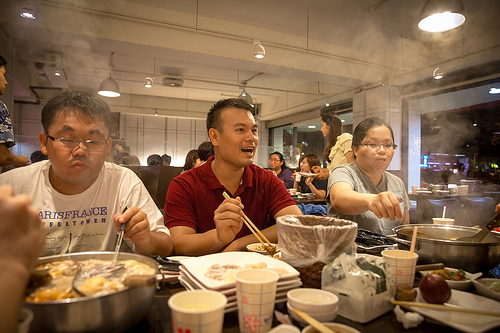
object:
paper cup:
[167, 289, 227, 333]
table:
[1, 245, 499, 332]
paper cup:
[235, 268, 279, 333]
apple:
[419, 272, 453, 305]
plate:
[179, 251, 301, 292]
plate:
[388, 281, 499, 330]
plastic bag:
[274, 214, 358, 268]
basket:
[276, 213, 357, 287]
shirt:
[163, 154, 297, 239]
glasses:
[358, 140, 398, 153]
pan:
[428, 188, 450, 196]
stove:
[408, 184, 496, 220]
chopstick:
[221, 188, 275, 250]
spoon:
[93, 205, 131, 274]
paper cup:
[379, 247, 418, 296]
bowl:
[287, 286, 339, 315]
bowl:
[285, 301, 339, 327]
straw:
[409, 225, 417, 256]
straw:
[440, 204, 446, 219]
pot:
[391, 224, 500, 274]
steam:
[315, 11, 480, 207]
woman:
[290, 154, 328, 198]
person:
[2, 84, 174, 257]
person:
[162, 97, 305, 253]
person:
[326, 115, 412, 234]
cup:
[458, 183, 468, 195]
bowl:
[22, 249, 159, 331]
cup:
[431, 216, 454, 224]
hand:
[212, 195, 245, 243]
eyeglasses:
[44, 131, 111, 152]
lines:
[171, 316, 218, 328]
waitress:
[311, 110, 353, 180]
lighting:
[252, 37, 266, 60]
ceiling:
[6, 1, 495, 118]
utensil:
[391, 222, 500, 276]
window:
[285, 125, 354, 166]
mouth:
[241, 145, 256, 157]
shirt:
[326, 162, 411, 236]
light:
[417, 10, 465, 33]